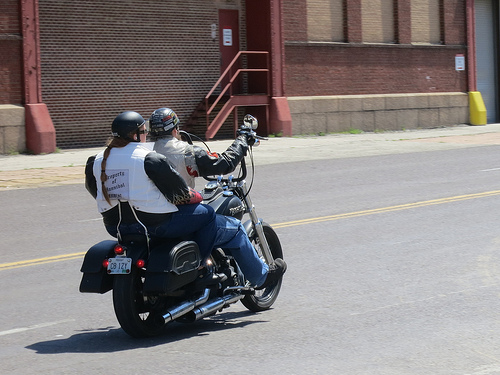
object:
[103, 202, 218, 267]
jeans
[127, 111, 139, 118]
sun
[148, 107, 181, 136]
helmet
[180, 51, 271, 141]
staircase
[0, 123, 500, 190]
sidewalk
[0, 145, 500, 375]
road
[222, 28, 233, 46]
sign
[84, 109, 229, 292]
people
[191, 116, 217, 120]
stairs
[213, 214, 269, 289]
jeans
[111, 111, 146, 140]
helmet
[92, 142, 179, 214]
vest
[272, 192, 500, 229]
line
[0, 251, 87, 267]
line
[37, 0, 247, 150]
wall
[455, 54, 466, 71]
sign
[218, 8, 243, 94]
door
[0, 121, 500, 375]
ground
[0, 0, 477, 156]
brick building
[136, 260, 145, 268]
lights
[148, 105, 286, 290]
man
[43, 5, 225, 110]
wall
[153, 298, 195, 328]
muffler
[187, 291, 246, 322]
muffler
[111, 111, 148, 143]
head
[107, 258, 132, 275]
license plate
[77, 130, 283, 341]
motorcycle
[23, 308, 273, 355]
shadow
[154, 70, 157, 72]
grout